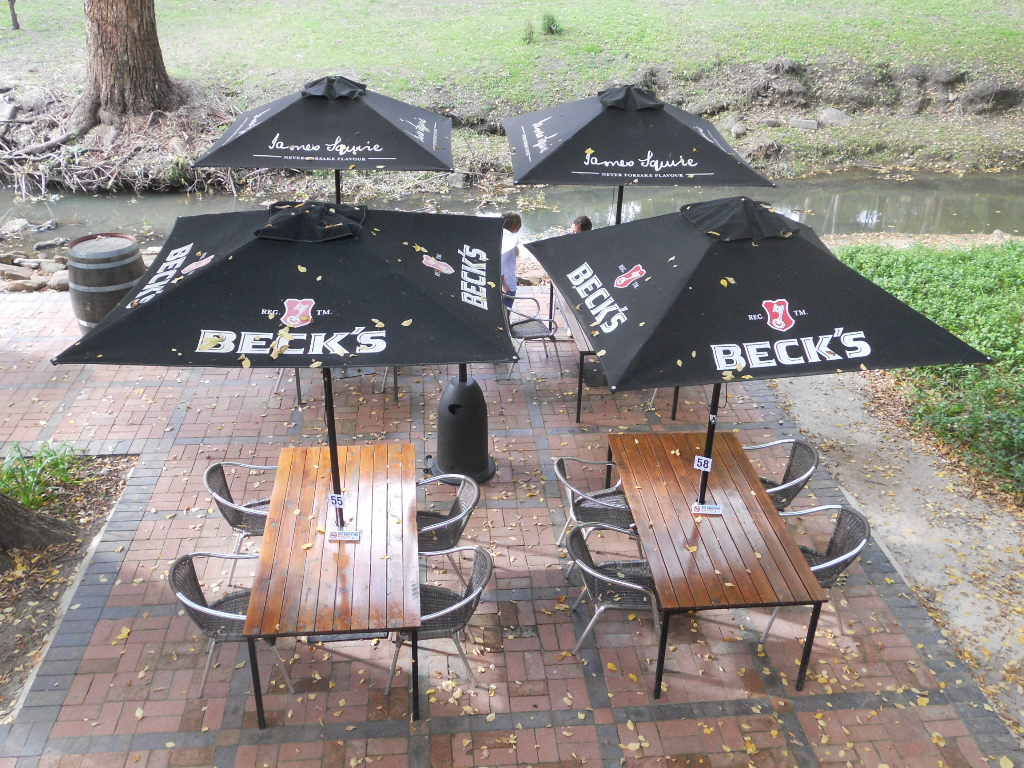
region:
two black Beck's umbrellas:
[59, 190, 999, 391]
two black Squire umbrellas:
[202, 70, 776, 195]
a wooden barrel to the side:
[60, 222, 150, 371]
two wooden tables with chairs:
[189, 432, 854, 698]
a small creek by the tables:
[16, 145, 1019, 282]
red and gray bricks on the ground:
[0, 281, 1013, 765]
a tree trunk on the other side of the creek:
[49, 15, 199, 148]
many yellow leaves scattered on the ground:
[29, 319, 1014, 765]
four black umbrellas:
[70, 58, 997, 404]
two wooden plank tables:
[241, 420, 833, 735]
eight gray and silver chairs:
[149, 439, 899, 700]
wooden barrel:
[69, 232, 150, 360]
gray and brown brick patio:
[6, 279, 1022, 754]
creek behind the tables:
[7, 172, 1020, 231]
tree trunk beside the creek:
[40, 7, 181, 140]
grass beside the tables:
[837, 224, 1002, 433]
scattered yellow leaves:
[34, 345, 1003, 766]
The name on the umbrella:
[198, 320, 395, 375]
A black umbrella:
[80, 193, 532, 397]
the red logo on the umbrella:
[270, 288, 327, 347]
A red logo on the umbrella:
[753, 289, 811, 344]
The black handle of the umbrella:
[306, 373, 357, 523]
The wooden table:
[246, 425, 424, 642]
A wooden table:
[618, 420, 819, 633]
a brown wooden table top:
[245, 440, 423, 634]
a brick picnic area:
[6, 341, 1021, 760]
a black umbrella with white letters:
[46, 202, 511, 373]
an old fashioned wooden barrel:
[62, 228, 146, 336]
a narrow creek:
[0, 170, 1022, 240]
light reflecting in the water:
[584, 198, 888, 240]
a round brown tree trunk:
[73, 0, 176, 128]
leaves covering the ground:
[3, 250, 1016, 766]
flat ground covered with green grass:
[3, 4, 1015, 81]